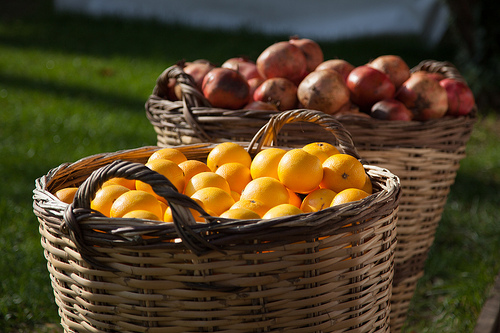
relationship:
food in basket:
[85, 158, 301, 222] [45, 168, 414, 304]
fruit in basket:
[235, 152, 326, 196] [50, 147, 421, 317]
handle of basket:
[49, 145, 212, 251] [29, 110, 404, 326]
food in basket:
[164, 34, 476, 124] [154, 47, 474, 254]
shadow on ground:
[23, 63, 136, 124] [23, 30, 143, 168]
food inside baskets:
[227, 32, 349, 211] [111, 40, 424, 317]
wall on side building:
[333, 6, 418, 31] [167, 5, 463, 45]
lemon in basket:
[277, 148, 323, 195] [40, 138, 394, 327]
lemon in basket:
[276, 143, 321, 194] [40, 138, 394, 327]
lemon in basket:
[33, 130, 407, 325] [191, 182, 231, 218]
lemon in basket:
[107, 185, 163, 215] [29, 110, 404, 326]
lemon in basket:
[204, 129, 246, 170] [29, 110, 404, 326]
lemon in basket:
[321, 147, 367, 190] [29, 110, 404, 326]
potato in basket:
[347, 61, 397, 108] [142, 32, 462, 256]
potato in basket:
[253, 27, 303, 81] [134, 35, 454, 270]